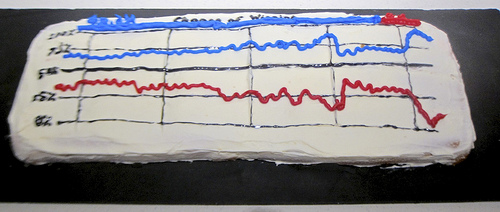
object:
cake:
[7, 12, 477, 168]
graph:
[33, 13, 443, 133]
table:
[1, 173, 500, 202]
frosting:
[76, 19, 150, 30]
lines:
[54, 119, 442, 133]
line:
[51, 94, 441, 101]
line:
[61, 62, 435, 73]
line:
[63, 28, 433, 61]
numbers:
[32, 26, 71, 127]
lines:
[73, 29, 97, 124]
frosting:
[380, 15, 415, 25]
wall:
[2, 1, 499, 8]